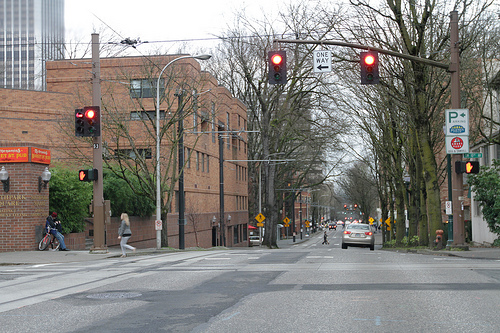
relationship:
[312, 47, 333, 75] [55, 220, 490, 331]
sign above street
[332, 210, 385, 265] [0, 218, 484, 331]
car driving down road